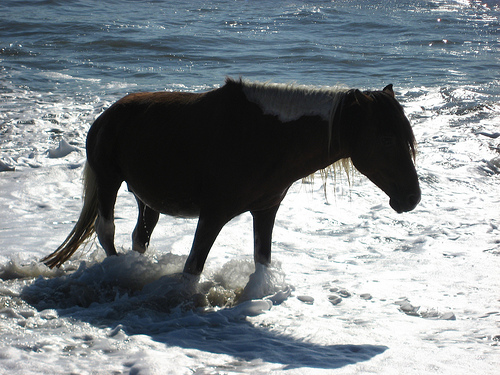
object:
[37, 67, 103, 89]
foam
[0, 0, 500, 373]
sea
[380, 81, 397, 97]
ear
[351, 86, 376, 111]
ear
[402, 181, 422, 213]
nose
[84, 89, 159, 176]
rear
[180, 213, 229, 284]
leg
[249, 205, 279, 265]
leg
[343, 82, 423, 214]
head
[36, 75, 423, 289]
horse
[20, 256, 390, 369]
shadow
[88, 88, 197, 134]
back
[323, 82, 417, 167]
hair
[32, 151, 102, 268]
tail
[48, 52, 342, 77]
ripples